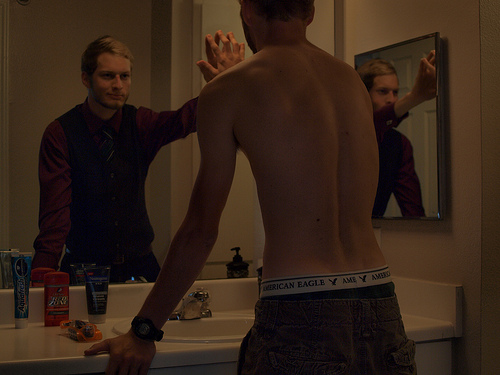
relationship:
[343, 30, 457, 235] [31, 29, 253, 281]
mirror to right of man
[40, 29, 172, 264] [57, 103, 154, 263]
man wears vest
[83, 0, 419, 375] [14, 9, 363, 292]
man looks in mirror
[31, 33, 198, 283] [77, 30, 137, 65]
man has hair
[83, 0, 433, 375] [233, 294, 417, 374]
man has pants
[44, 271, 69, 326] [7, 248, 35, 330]
container next to toothpaste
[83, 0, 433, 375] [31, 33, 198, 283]
man looking at man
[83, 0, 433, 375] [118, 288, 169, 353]
man wearing watch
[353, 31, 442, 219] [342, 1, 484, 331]
mirror on wall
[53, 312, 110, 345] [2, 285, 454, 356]
razor sitting on counter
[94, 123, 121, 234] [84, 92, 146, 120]
tie around man's neck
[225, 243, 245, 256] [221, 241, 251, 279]
pump of bottle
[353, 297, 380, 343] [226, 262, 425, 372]
belt loop of clothing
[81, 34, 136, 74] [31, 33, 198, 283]
hair of man